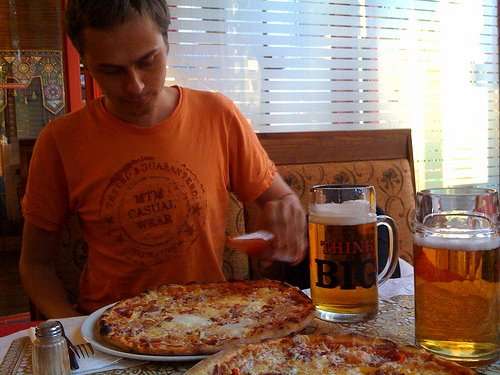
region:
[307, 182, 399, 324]
A large mug of beer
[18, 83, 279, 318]
An orange t-shirt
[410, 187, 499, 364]
A large mug of beer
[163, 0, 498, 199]
Partially closed mini blinds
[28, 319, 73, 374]
A pepper shaker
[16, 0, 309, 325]
A man pouring hot sauce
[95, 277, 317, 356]
A large, uncut pizza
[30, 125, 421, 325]
A padded wooden bench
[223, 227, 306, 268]
A bottle of hot sauce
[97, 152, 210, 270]
A round logo on an orange shirt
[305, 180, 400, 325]
A very large cup of delicious beer.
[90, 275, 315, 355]
A scrumptious large pizza in a man's plate.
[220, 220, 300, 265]
A bottle of hot sauce.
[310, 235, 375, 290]
A message telling customers to Think Big.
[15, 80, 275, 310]
An orange shirt worn by a young man.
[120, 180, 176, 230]
The brand is MTM Casual Wear.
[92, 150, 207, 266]
The entire logo of the brand of the shirt.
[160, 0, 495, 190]
A large window behind the man.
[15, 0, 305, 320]
A person who's having a very good day.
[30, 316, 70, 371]
A bottle of pepper on a table.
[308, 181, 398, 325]
clear beer mug that says Think Big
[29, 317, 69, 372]
glass pepper shaker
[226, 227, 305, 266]
tabasco sauce in hand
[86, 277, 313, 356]
entire cheese pizza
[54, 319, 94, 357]
upside down silver fork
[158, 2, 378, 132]
white closed window blinds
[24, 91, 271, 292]
orange shirt with black writing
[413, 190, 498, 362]
clear beer mug with beer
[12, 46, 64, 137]
mirror in the background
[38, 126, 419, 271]
wood and cloth booth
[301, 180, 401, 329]
mug of beer with foam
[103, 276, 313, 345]
cheese pizza on a plate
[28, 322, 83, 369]
pepper shaker on the table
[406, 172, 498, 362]
large mug of beer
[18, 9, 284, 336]
man eating pizza at a restaurant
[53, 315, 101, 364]
fork at a restaurant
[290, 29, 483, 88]
horizontal blinds over the window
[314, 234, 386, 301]
think bog mug of beer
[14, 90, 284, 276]
man in orange t-shirt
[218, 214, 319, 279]
hot sauce being shaken on pizza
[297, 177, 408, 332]
large mug of beer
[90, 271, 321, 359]
plate of pizza in a restaurant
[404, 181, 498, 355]
mug full of beer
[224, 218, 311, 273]
hot sauce being poured on pizza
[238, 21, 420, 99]
white blinds on a window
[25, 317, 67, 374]
pepper shaker on table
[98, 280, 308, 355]
round greasy cheese pizza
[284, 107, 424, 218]
booth in a restaurant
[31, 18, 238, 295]
man in an orange t-shirt